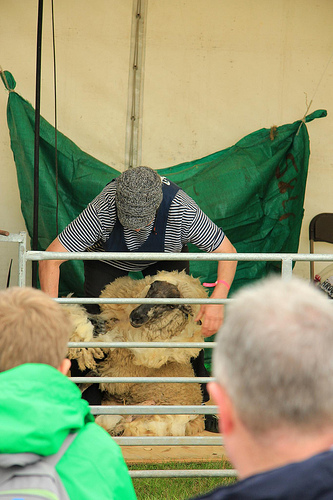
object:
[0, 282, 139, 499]
people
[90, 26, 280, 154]
outdoors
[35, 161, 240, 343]
man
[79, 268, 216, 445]
sheep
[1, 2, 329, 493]
photo